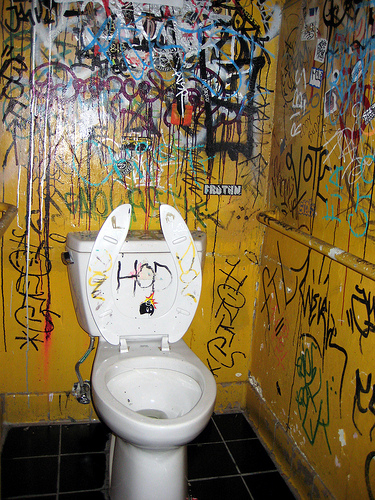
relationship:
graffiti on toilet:
[76, 198, 205, 326] [57, 191, 222, 500]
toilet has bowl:
[57, 191, 222, 500] [83, 344, 225, 454]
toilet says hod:
[57, 191, 222, 500] [103, 251, 183, 301]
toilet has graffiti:
[57, 191, 222, 500] [76, 198, 205, 326]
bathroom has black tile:
[9, 5, 374, 497] [4, 412, 295, 497]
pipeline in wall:
[64, 334, 94, 410] [6, 293, 109, 420]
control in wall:
[65, 371, 94, 408] [6, 293, 109, 420]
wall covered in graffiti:
[0, 0, 375, 498] [0, 0, 369, 435]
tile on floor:
[4, 412, 295, 497] [4, 412, 295, 497]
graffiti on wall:
[0, 0, 372, 498] [0, 0, 369, 435]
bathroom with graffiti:
[9, 5, 374, 497] [0, 0, 372, 498]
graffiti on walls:
[0, 0, 372, 498] [0, 0, 369, 435]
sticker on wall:
[200, 174, 247, 204] [0, 0, 375, 498]